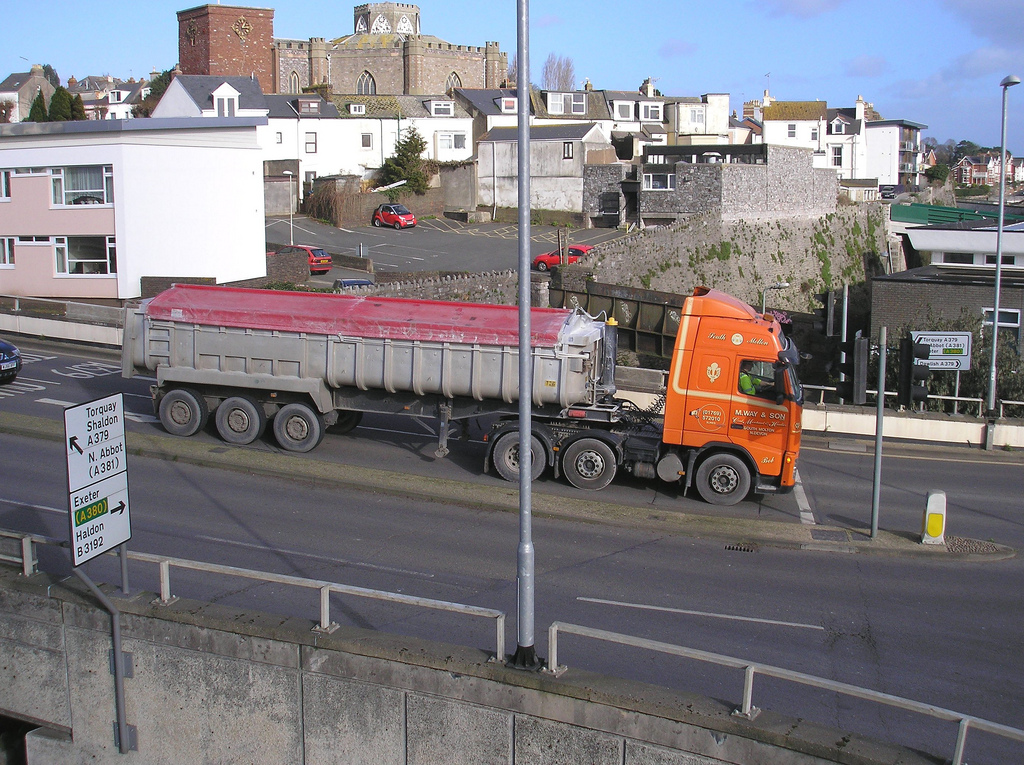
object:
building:
[276, 2, 512, 102]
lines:
[573, 588, 827, 640]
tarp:
[153, 277, 577, 344]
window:
[50, 162, 119, 203]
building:
[867, 268, 1021, 383]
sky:
[19, 5, 1016, 157]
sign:
[54, 399, 134, 494]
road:
[6, 286, 1010, 761]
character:
[68, 543, 77, 557]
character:
[78, 398, 124, 419]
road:
[2, 333, 1023, 761]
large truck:
[125, 282, 810, 508]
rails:
[544, 613, 1021, 762]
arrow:
[67, 433, 89, 460]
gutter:
[725, 534, 764, 548]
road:
[208, 474, 989, 704]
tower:
[351, 1, 419, 39]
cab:
[666, 287, 801, 506]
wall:
[158, 188, 223, 233]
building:
[0, 113, 280, 301]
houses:
[478, 120, 617, 215]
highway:
[2, 308, 1023, 762]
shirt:
[740, 371, 754, 395]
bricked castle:
[176, 0, 527, 121]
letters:
[84, 410, 97, 421]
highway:
[11, 362, 985, 739]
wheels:
[153, 379, 201, 439]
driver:
[741, 364, 766, 395]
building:
[102, 77, 379, 215]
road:
[191, 454, 993, 722]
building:
[175, 4, 515, 104]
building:
[0, 61, 67, 127]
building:
[273, 89, 410, 204]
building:
[384, 91, 475, 169]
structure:
[67, 619, 310, 761]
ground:
[6, 322, 992, 757]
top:
[60, 387, 128, 426]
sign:
[69, 475, 141, 569]